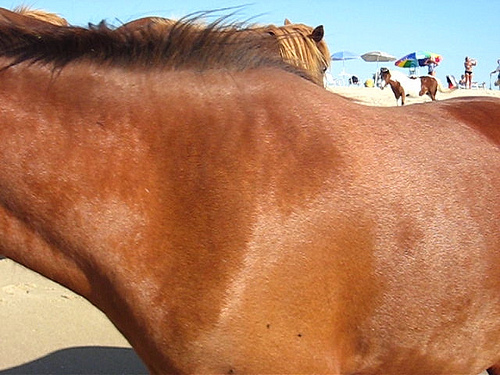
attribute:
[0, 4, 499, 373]
horse — big, standing, brown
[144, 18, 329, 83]
mane — blonde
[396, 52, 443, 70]
umbrella — multi colored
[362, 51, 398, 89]
umbrella — white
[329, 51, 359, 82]
umbrella — blue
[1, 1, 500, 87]
sky — blue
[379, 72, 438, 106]
horse — white, brown